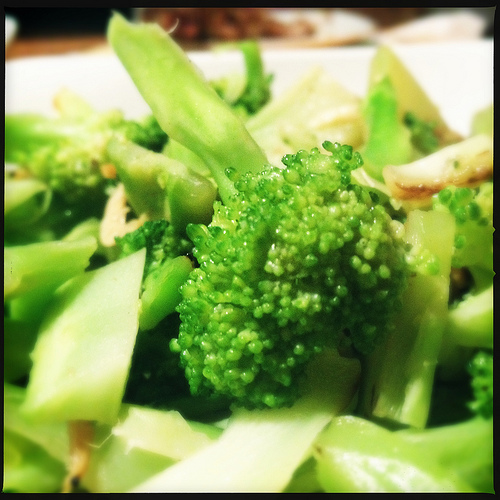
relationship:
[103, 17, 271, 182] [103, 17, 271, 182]
broccoli has broccoli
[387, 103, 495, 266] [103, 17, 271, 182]
vegetable has broccoli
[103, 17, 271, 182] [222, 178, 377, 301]
broccoli has grain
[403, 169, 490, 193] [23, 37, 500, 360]
char from cooking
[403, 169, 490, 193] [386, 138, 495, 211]
char from fry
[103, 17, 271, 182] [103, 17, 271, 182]
broccoli from broccoli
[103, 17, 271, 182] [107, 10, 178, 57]
broccoli sticking out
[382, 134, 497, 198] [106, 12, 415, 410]
onion on top of broccoli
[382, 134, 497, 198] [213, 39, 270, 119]
onion on top of broccoli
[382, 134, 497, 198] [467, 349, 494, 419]
onion on top of broccoli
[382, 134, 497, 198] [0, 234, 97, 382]
onion on top of broccoli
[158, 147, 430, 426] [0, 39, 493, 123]
broccoli on dish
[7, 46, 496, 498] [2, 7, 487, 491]
dish on table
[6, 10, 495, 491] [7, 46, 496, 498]
meal on dish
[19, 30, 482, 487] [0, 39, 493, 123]
food on dish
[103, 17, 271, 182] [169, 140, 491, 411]
broccoli of broccoli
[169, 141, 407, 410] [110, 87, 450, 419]
buds of broccoli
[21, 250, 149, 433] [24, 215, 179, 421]
stem of broccoli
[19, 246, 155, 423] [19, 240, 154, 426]
spear of broccoli